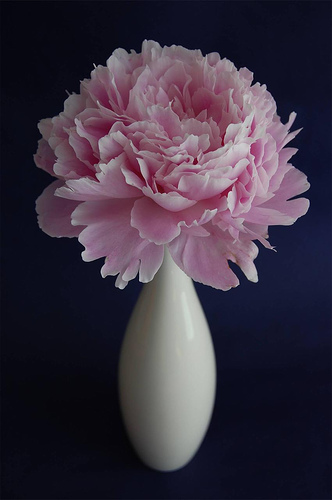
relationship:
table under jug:
[0, 365, 331, 499] [119, 245, 217, 472]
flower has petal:
[30, 37, 313, 293] [129, 194, 218, 247]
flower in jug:
[30, 37, 313, 293] [119, 245, 217, 472]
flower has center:
[30, 37, 313, 293] [156, 131, 180, 155]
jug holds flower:
[119, 245, 217, 472] [30, 37, 313, 293]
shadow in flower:
[89, 121, 121, 139] [30, 37, 313, 293]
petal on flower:
[129, 194, 218, 247] [30, 37, 313, 293]